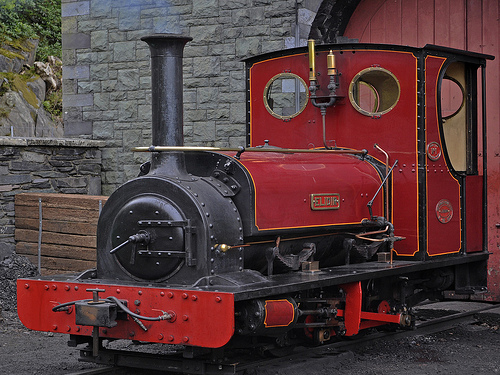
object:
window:
[267, 75, 308, 115]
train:
[16, 34, 494, 373]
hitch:
[51, 288, 172, 357]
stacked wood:
[13, 192, 114, 275]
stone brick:
[90, 63, 108, 80]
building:
[58, 0, 319, 195]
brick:
[82, 110, 102, 121]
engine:
[93, 36, 243, 284]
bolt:
[183, 315, 189, 321]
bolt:
[167, 292, 174, 298]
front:
[18, 279, 234, 347]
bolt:
[214, 297, 221, 303]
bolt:
[191, 295, 196, 300]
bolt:
[182, 293, 188, 298]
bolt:
[182, 336, 189, 342]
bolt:
[168, 335, 174, 341]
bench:
[13, 190, 108, 275]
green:
[0, 0, 58, 50]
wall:
[58, 1, 292, 138]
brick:
[191, 3, 218, 18]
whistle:
[308, 39, 316, 81]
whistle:
[327, 50, 336, 74]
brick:
[192, 56, 221, 77]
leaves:
[23, 24, 27, 29]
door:
[425, 55, 486, 256]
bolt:
[157, 333, 163, 339]